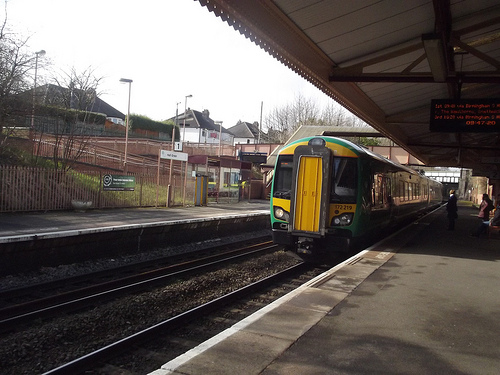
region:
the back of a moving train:
[255, 143, 367, 256]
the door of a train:
[297, 147, 324, 242]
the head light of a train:
[270, 196, 295, 230]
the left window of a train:
[270, 164, 297, 195]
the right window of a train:
[320, 162, 361, 203]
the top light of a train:
[307, 136, 331, 151]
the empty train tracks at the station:
[144, 254, 184, 286]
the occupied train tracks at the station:
[233, 265, 284, 306]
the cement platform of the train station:
[402, 252, 481, 345]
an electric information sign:
[432, 92, 499, 119]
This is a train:
[215, 126, 444, 255]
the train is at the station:
[261, 105, 447, 259]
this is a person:
[423, 177, 472, 247]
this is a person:
[467, 183, 493, 239]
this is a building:
[171, 94, 242, 206]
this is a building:
[23, 65, 128, 167]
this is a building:
[233, 111, 280, 172]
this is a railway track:
[30, 190, 143, 362]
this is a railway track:
[86, 242, 204, 324]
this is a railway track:
[187, 233, 267, 296]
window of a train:
[269, 154, 306, 196]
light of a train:
[272, 206, 289, 219]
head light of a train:
[331, 208, 357, 232]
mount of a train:
[293, 235, 321, 251]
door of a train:
[295, 148, 333, 240]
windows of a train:
[368, 160, 431, 198]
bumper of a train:
[268, 225, 361, 262]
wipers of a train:
[273, 180, 290, 200]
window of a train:
[425, 179, 442, 199]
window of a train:
[359, 165, 396, 192]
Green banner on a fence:
[102, 173, 135, 190]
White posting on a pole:
[157, 148, 188, 161]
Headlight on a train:
[272, 208, 287, 219]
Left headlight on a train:
[333, 211, 351, 226]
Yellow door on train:
[296, 153, 323, 229]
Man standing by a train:
[444, 187, 459, 229]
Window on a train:
[397, 180, 404, 203]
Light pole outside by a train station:
[118, 77, 131, 168]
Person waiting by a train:
[475, 190, 492, 234]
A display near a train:
[430, 98, 498, 128]